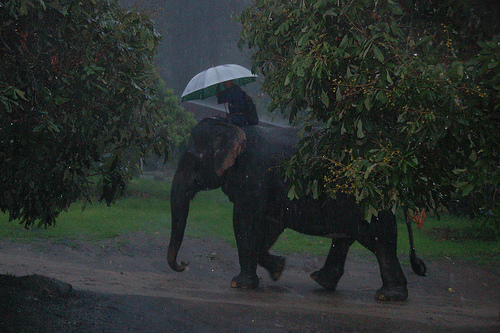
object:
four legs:
[235, 211, 408, 272]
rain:
[0, 0, 499, 333]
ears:
[207, 122, 247, 178]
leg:
[232, 203, 260, 277]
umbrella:
[180, 63, 258, 116]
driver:
[216, 80, 260, 126]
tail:
[405, 203, 430, 277]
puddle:
[0, 252, 207, 299]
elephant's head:
[165, 116, 250, 271]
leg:
[363, 228, 408, 283]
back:
[237, 115, 372, 157]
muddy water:
[23, 280, 498, 307]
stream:
[136, 281, 423, 315]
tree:
[239, 0, 499, 240]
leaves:
[236, 0, 497, 226]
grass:
[0, 172, 500, 248]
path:
[0, 236, 499, 331]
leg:
[259, 219, 279, 276]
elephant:
[165, 113, 432, 301]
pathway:
[3, 229, 498, 330]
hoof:
[266, 255, 288, 281]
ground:
[0, 236, 499, 333]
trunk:
[165, 157, 198, 275]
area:
[0, 0, 499, 333]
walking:
[197, 200, 294, 321]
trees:
[0, 0, 197, 233]